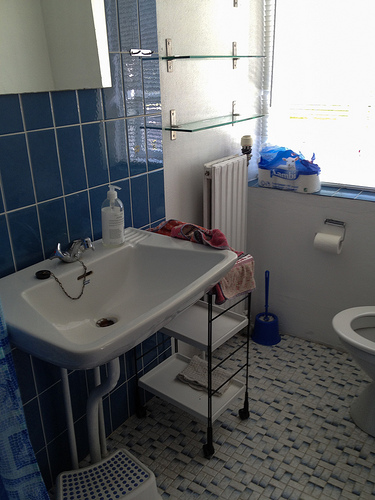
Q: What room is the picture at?
A: It is at the bathroom.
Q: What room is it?
A: It is a bathroom.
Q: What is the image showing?
A: It is showing a bathroom.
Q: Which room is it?
A: It is a bathroom.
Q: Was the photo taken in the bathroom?
A: Yes, it was taken in the bathroom.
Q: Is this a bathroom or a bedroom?
A: It is a bathroom.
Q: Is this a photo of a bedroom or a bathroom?
A: It is showing a bathroom.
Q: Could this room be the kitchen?
A: No, it is the bathroom.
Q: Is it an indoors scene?
A: Yes, it is indoors.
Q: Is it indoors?
A: Yes, it is indoors.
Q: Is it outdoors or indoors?
A: It is indoors.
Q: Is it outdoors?
A: No, it is indoors.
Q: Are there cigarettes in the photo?
A: No, there are no cigarettes.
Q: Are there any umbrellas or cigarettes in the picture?
A: No, there are no cigarettes or umbrellas.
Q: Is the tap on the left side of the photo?
A: Yes, the tap is on the left of the image.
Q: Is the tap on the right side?
A: No, the tap is on the left of the image.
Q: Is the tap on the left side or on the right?
A: The tap is on the left of the image.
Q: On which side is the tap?
A: The tap is on the left of the image.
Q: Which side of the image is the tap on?
A: The tap is on the left of the image.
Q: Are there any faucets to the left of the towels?
A: Yes, there is a faucet to the left of the towels.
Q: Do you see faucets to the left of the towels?
A: Yes, there is a faucet to the left of the towels.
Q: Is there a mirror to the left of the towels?
A: No, there is a faucet to the left of the towels.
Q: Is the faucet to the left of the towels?
A: Yes, the faucet is to the left of the towels.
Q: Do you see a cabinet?
A: No, there are no cabinets.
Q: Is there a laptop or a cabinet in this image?
A: No, there are no cabinets or laptops.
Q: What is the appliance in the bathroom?
A: The appliance is a radiator.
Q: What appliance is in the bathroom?
A: The appliance is a radiator.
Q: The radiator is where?
A: The radiator is in the bathroom.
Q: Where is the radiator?
A: The radiator is in the bathroom.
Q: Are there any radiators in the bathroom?
A: Yes, there is a radiator in the bathroom.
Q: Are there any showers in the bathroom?
A: No, there is a radiator in the bathroom.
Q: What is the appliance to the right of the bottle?
A: The appliance is a radiator.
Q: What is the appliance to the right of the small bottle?
A: The appliance is a radiator.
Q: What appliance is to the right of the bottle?
A: The appliance is a radiator.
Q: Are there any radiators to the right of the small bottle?
A: Yes, there is a radiator to the right of the bottle.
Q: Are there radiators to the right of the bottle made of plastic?
A: Yes, there is a radiator to the right of the bottle.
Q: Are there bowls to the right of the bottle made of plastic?
A: No, there is a radiator to the right of the bottle.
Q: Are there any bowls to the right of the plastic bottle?
A: No, there is a radiator to the right of the bottle.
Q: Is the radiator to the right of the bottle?
A: Yes, the radiator is to the right of the bottle.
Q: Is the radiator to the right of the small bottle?
A: Yes, the radiator is to the right of the bottle.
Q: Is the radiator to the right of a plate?
A: No, the radiator is to the right of the bottle.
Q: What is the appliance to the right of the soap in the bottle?
A: The appliance is a radiator.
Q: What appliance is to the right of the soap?
A: The appliance is a radiator.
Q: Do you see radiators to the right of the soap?
A: Yes, there is a radiator to the right of the soap.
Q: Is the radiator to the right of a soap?
A: Yes, the radiator is to the right of a soap.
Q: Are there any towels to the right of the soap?
A: Yes, there are towels to the right of the soap.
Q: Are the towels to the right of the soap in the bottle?
A: Yes, the towels are to the right of the soap.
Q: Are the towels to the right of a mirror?
A: No, the towels are to the right of the soap.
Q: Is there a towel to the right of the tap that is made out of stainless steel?
A: Yes, there are towels to the right of the faucet.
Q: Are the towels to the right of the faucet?
A: Yes, the towels are to the right of the faucet.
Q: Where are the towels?
A: The towels are in the bathroom.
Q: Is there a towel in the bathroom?
A: Yes, there are towels in the bathroom.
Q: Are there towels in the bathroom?
A: Yes, there are towels in the bathroom.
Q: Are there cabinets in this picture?
A: No, there are no cabinets.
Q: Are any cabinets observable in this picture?
A: No, there are no cabinets.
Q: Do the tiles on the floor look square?
A: Yes, the tiles are square.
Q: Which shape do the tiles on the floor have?
A: The tiles have square shape.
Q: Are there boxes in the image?
A: No, there are no boxes.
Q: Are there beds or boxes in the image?
A: No, there are no boxes or beds.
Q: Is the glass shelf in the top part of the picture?
A: Yes, the shelf is in the top of the image.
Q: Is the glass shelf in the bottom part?
A: No, the shelf is in the top of the image.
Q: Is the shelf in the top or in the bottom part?
A: The shelf is in the top of the image.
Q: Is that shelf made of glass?
A: Yes, the shelf is made of glass.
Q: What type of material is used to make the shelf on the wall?
A: The shelf is made of glass.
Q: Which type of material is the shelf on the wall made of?
A: The shelf is made of glass.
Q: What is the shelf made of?
A: The shelf is made of glass.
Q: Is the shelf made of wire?
A: No, the shelf is made of glass.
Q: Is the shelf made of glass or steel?
A: The shelf is made of glass.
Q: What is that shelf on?
A: The shelf is on the wall.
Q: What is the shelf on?
A: The shelf is on the wall.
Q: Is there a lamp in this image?
A: No, there are no lamps.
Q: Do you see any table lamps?
A: No, there are no table lamps.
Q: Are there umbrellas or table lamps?
A: No, there are no table lamps or umbrellas.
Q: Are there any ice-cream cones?
A: No, there are no ice-cream cones.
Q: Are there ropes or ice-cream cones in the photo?
A: No, there are no ice-cream cones or ropes.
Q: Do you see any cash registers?
A: No, there are no cash registers.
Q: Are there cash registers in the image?
A: No, there are no cash registers.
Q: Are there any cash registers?
A: No, there are no cash registers.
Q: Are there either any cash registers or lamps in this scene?
A: No, there are no cash registers or lamps.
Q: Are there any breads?
A: No, there are no breads.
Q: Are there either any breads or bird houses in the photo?
A: No, there are no breads or bird houses.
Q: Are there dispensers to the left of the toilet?
A: No, there is a tray to the left of the toilet.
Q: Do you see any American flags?
A: No, there are no American flags.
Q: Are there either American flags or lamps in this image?
A: No, there are no American flags or lamps.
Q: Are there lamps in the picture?
A: No, there are no lamps.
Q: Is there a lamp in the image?
A: No, there are no lamps.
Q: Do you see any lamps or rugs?
A: No, there are no lamps or rugs.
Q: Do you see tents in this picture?
A: No, there are no tents.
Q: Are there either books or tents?
A: No, there are no tents or books.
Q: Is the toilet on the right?
A: Yes, the toilet is on the right of the image.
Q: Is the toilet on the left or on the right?
A: The toilet is on the right of the image.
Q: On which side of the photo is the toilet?
A: The toilet is on the right of the image.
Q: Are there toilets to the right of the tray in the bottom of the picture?
A: Yes, there is a toilet to the right of the tray.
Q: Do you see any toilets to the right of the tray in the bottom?
A: Yes, there is a toilet to the right of the tray.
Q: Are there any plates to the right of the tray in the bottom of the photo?
A: No, there is a toilet to the right of the tray.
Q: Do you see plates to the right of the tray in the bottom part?
A: No, there is a toilet to the right of the tray.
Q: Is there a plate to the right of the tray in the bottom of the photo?
A: No, there is a toilet to the right of the tray.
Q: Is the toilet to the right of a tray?
A: Yes, the toilet is to the right of a tray.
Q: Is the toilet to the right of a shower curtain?
A: No, the toilet is to the right of a tray.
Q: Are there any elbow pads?
A: No, there are no elbow pads.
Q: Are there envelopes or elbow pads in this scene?
A: No, there are no elbow pads or envelopes.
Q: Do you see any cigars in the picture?
A: No, there are no cigars.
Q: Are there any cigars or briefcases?
A: No, there are no cigars or briefcases.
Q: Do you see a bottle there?
A: Yes, there is a bottle.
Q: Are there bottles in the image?
A: Yes, there is a bottle.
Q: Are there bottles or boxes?
A: Yes, there is a bottle.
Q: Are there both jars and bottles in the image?
A: No, there is a bottle but no jars.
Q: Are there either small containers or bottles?
A: Yes, there is a small bottle.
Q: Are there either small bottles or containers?
A: Yes, there is a small bottle.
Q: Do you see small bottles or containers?
A: Yes, there is a small bottle.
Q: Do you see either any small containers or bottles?
A: Yes, there is a small bottle.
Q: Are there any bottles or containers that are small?
A: Yes, the bottle is small.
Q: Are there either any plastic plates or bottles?
A: Yes, there is a plastic bottle.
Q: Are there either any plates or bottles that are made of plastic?
A: Yes, the bottle is made of plastic.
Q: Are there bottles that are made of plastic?
A: Yes, there is a bottle that is made of plastic.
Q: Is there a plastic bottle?
A: Yes, there is a bottle that is made of plastic.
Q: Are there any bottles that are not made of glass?
A: Yes, there is a bottle that is made of plastic.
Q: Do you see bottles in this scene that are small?
A: Yes, there is a small bottle.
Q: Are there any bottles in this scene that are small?
A: Yes, there is a bottle that is small.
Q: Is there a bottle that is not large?
A: Yes, there is a small bottle.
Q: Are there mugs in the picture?
A: No, there are no mugs.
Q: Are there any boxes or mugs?
A: No, there are no mugs or boxes.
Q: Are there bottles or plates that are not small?
A: No, there is a bottle but it is small.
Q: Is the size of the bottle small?
A: Yes, the bottle is small.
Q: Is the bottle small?
A: Yes, the bottle is small.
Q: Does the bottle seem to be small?
A: Yes, the bottle is small.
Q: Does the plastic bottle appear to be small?
A: Yes, the bottle is small.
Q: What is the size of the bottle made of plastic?
A: The bottle is small.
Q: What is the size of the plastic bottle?
A: The bottle is small.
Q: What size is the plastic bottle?
A: The bottle is small.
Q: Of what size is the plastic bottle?
A: The bottle is small.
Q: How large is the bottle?
A: The bottle is small.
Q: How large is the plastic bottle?
A: The bottle is small.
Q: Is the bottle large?
A: No, the bottle is small.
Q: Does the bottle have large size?
A: No, the bottle is small.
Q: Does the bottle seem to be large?
A: No, the bottle is small.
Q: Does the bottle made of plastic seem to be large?
A: No, the bottle is small.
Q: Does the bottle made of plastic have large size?
A: No, the bottle is small.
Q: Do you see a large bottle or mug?
A: No, there is a bottle but it is small.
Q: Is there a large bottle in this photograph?
A: No, there is a bottle but it is small.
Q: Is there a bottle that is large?
A: No, there is a bottle but it is small.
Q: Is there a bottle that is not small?
A: No, there is a bottle but it is small.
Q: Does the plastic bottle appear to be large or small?
A: The bottle is small.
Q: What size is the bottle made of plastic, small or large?
A: The bottle is small.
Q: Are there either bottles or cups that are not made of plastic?
A: No, there is a bottle but it is made of plastic.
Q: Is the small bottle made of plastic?
A: Yes, the bottle is made of plastic.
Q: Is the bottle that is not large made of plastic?
A: Yes, the bottle is made of plastic.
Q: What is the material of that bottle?
A: The bottle is made of plastic.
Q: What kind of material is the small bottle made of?
A: The bottle is made of plastic.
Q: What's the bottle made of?
A: The bottle is made of plastic.